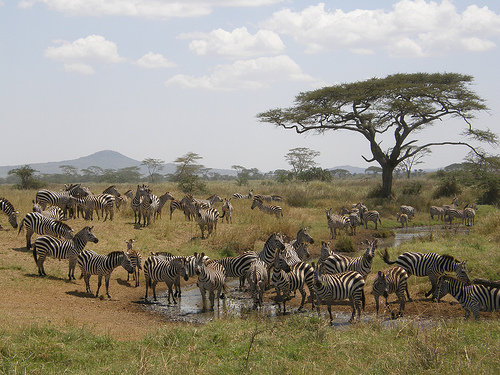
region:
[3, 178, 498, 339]
zeal of zebras at watering hole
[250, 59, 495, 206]
deciduous tree on the African plains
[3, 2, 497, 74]
white clouds in blue sky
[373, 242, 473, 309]
zebra swinging its tail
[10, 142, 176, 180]
cone shaped mountain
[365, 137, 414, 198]
tree trunk of large tree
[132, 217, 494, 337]
water at the zebra's watering hole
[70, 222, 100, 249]
zebra's head and neck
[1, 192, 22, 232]
zebra eating grass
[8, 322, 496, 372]
green grass on the African plains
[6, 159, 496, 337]
there are a lot of zebras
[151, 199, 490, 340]
there is a small creek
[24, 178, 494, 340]
these are wild animals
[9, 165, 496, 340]
a herd of zebras in the wild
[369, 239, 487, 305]
the zebra is wagging its tail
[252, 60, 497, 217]
this is a tall tree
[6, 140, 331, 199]
trees in the distance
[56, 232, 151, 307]
the zebra is on the dirt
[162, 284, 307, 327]
the water looks muddy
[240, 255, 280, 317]
this zebra is taking a drink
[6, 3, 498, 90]
these are the clouds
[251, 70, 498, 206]
this is green tree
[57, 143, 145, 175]
this is a mountain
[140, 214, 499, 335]
this is a creek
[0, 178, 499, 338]
these are striped zebra's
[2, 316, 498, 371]
this is the green grass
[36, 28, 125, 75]
this is a white cloud in the sky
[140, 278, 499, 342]
this is some water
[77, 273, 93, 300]
these are the zebra's legs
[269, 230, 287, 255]
the head of the zebra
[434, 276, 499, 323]
a zebra in a herd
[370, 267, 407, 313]
a zebra in a herd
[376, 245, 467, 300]
a zebra in a herd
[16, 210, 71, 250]
a zebra in a herd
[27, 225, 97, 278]
a zebra in a herd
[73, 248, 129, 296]
a zebra in a herd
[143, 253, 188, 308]
a zebra in a herd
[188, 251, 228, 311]
a zebra in a herd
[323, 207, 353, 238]
a zebra in a herd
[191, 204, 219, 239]
a zebra in a herd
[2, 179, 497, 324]
Large herd of zebras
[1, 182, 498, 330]
Large gathering of zebras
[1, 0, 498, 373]
Zebras and a safari on a sunny day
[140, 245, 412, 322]
Zebras standing in puddles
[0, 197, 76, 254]
Two zebras grazing on grass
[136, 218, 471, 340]
Small body of water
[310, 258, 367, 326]
Black and white zebra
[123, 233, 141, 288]
Small brown and white zebra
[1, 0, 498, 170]
White clouds in a light blue sky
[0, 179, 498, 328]
Zebras standing around